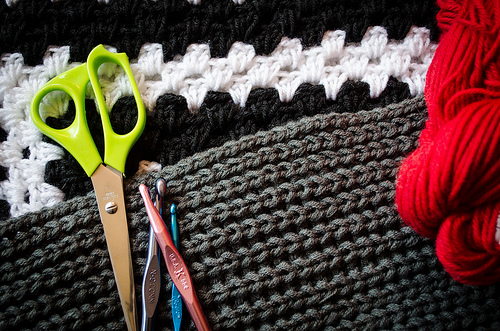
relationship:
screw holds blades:
[104, 199, 120, 216] [91, 162, 139, 331]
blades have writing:
[91, 162, 139, 331] [98, 187, 123, 201]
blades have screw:
[91, 162, 139, 331] [104, 199, 120, 216]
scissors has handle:
[27, 40, 162, 330] [27, 42, 149, 177]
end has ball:
[155, 177, 170, 203] [152, 174, 171, 205]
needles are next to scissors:
[133, 175, 218, 331] [27, 40, 162, 330]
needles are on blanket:
[133, 175, 218, 331] [3, 0, 421, 331]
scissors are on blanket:
[27, 40, 162, 330] [3, 0, 421, 331]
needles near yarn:
[133, 175, 218, 331] [393, 1, 499, 277]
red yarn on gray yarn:
[393, 1, 499, 277] [0, 248, 420, 329]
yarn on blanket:
[393, 1, 499, 277] [3, 0, 421, 331]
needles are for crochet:
[133, 175, 218, 331] [3, 0, 421, 331]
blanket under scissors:
[3, 0, 421, 331] [27, 40, 162, 330]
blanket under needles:
[3, 0, 421, 331] [133, 175, 218, 331]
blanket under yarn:
[3, 0, 421, 331] [393, 1, 499, 277]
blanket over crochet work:
[3, 0, 421, 331] [4, 2, 407, 98]